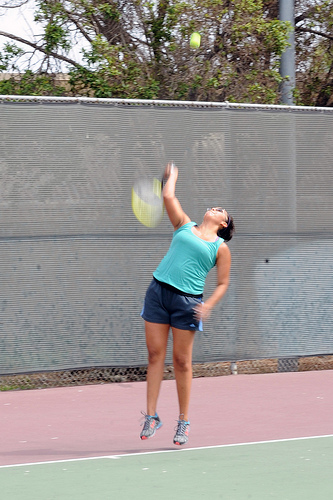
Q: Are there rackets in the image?
A: Yes, there is a racket.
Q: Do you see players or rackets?
A: Yes, there is a racket.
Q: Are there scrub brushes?
A: No, there are no scrub brushes.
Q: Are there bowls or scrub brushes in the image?
A: No, there are no scrub brushes or bowls.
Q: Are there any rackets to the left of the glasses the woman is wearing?
A: Yes, there is a racket to the left of the glasses.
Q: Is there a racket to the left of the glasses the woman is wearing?
A: Yes, there is a racket to the left of the glasses.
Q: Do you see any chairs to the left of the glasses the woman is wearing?
A: No, there is a racket to the left of the glasses.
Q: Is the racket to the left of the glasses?
A: Yes, the racket is to the left of the glasses.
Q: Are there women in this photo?
A: Yes, there is a woman.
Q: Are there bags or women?
A: Yes, there is a woman.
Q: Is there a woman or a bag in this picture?
A: Yes, there is a woman.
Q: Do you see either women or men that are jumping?
A: Yes, the woman is jumping.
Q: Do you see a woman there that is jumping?
A: Yes, there is a woman that is jumping.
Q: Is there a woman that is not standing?
A: Yes, there is a woman that is jumping.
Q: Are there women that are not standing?
A: Yes, there is a woman that is jumping.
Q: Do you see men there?
A: No, there are no men.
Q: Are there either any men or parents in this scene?
A: No, there are no men or parents.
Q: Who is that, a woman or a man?
A: That is a woman.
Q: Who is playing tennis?
A: The woman is playing tennis.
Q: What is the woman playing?
A: The woman is playing tennis.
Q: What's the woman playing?
A: The woman is playing tennis.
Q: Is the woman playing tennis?
A: Yes, the woman is playing tennis.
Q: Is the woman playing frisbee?
A: No, the woman is playing tennis.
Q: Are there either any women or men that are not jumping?
A: No, there is a woman but she is jumping.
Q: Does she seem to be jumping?
A: Yes, the woman is jumping.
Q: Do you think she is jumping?
A: Yes, the woman is jumping.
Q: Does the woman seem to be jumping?
A: Yes, the woman is jumping.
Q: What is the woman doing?
A: The woman is jumping.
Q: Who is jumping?
A: The woman is jumping.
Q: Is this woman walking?
A: No, the woman is jumping.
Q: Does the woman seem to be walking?
A: No, the woman is jumping.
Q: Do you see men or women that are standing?
A: No, there is a woman but she is jumping.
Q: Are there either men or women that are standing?
A: No, there is a woman but she is jumping.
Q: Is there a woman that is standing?
A: No, there is a woman but she is jumping.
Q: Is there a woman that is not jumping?
A: No, there is a woman but she is jumping.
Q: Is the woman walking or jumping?
A: The woman is jumping.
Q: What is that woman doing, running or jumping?
A: The woman is jumping.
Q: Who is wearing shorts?
A: The woman is wearing shorts.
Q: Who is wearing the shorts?
A: The woman is wearing shorts.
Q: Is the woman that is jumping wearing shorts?
A: Yes, the woman is wearing shorts.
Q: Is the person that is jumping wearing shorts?
A: Yes, the woman is wearing shorts.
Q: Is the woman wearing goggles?
A: No, the woman is wearing shorts.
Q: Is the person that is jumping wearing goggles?
A: No, the woman is wearing shorts.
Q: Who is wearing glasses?
A: The woman is wearing glasses.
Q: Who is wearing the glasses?
A: The woman is wearing glasses.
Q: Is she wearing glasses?
A: Yes, the woman is wearing glasses.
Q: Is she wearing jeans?
A: No, the woman is wearing glasses.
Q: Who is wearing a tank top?
A: The woman is wearing a tank top.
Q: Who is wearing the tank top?
A: The woman is wearing a tank top.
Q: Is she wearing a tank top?
A: Yes, the woman is wearing a tank top.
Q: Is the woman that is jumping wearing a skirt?
A: No, the woman is wearing a tank top.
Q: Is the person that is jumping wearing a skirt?
A: No, the woman is wearing a tank top.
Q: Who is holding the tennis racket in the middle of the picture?
A: The woman is holding the tennis racket.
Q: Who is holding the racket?
A: The woman is holding the tennis racket.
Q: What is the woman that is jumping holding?
A: The woman is holding the racket.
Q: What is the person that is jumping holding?
A: The woman is holding the racket.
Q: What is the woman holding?
A: The woman is holding the racket.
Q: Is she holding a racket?
A: Yes, the woman is holding a racket.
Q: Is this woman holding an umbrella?
A: No, the woman is holding a racket.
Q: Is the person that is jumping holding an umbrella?
A: No, the woman is holding a racket.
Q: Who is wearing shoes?
A: The woman is wearing shoes.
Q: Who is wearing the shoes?
A: The woman is wearing shoes.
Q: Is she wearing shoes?
A: Yes, the woman is wearing shoes.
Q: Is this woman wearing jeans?
A: No, the woman is wearing shoes.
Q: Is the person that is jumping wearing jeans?
A: No, the woman is wearing shoes.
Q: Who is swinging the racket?
A: The woman is swinging the racket.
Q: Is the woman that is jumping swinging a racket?
A: Yes, the woman is swinging a racket.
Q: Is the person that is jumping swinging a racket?
A: Yes, the woman is swinging a racket.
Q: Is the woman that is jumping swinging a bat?
A: No, the woman is swinging a racket.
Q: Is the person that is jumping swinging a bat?
A: No, the woman is swinging a racket.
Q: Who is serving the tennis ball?
A: The woman is serving the tennis ball.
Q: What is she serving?
A: The woman is serving a tennis ball.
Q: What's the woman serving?
A: The woman is serving a tennis ball.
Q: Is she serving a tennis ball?
A: Yes, the woman is serving a tennis ball.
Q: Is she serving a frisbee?
A: No, the woman is serving a tennis ball.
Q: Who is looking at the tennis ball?
A: The woman is looking at the tennis ball.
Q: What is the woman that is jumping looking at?
A: The woman is looking at the tennis ball.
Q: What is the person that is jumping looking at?
A: The woman is looking at the tennis ball.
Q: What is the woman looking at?
A: The woman is looking at the tennis ball.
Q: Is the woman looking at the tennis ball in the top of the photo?
A: Yes, the woman is looking at the tennis ball.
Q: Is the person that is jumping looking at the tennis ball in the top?
A: Yes, the woman is looking at the tennis ball.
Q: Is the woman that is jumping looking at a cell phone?
A: No, the woman is looking at the tennis ball.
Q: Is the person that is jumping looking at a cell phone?
A: No, the woman is looking at the tennis ball.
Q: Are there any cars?
A: No, there are no cars.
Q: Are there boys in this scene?
A: No, there are no boys.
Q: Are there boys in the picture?
A: No, there are no boys.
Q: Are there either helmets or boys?
A: No, there are no boys or helmets.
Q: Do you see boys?
A: No, there are no boys.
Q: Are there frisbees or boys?
A: No, there are no boys or frisbees.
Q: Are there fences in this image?
A: Yes, there is a fence.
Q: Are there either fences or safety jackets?
A: Yes, there is a fence.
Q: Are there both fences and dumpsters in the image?
A: No, there is a fence but no dumpsters.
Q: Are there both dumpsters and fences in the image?
A: No, there is a fence but no dumpsters.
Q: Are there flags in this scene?
A: No, there are no flags.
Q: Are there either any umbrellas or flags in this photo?
A: No, there are no flags or umbrellas.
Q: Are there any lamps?
A: No, there are no lamps.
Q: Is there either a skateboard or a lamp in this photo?
A: No, there are no lamps or skateboards.